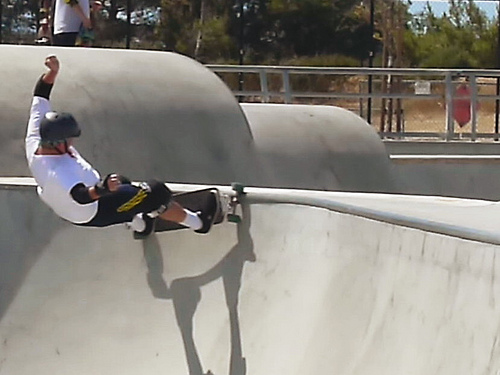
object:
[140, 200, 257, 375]
shadow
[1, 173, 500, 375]
pike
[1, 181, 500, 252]
edge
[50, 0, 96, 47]
person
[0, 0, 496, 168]
background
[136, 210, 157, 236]
shoe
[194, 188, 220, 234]
shoe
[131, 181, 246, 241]
skateboard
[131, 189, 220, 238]
feet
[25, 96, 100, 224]
shirt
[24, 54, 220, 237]
guy